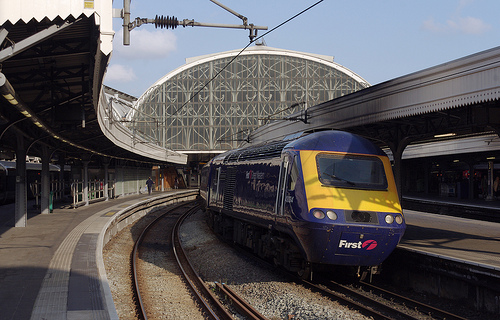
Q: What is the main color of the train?
A: Purple.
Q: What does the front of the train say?
A: First.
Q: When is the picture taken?
A: Daytime.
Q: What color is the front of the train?
A: Yellow.